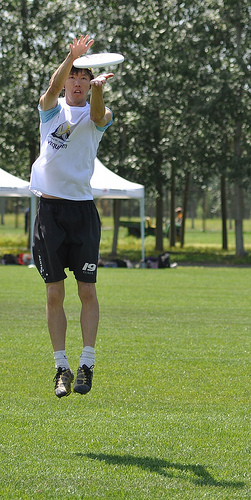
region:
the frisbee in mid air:
[72, 52, 123, 67]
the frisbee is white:
[73, 52, 124, 67]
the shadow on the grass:
[70, 452, 243, 487]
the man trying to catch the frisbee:
[28, 34, 123, 397]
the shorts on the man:
[31, 195, 101, 282]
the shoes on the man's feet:
[52, 364, 93, 397]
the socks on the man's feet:
[52, 345, 94, 371]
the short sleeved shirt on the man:
[28, 96, 112, 198]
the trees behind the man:
[0, 0, 250, 258]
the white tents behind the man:
[0, 156, 144, 267]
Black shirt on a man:
[31, 195, 101, 285]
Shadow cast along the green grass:
[71, 448, 247, 488]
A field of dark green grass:
[2, 266, 250, 498]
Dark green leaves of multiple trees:
[5, 4, 245, 173]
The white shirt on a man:
[29, 95, 111, 199]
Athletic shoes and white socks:
[50, 345, 96, 398]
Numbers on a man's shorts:
[81, 261, 95, 271]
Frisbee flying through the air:
[71, 52, 124, 69]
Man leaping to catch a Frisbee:
[27, 35, 124, 398]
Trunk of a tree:
[233, 188, 250, 257]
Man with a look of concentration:
[62, 64, 91, 106]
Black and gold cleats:
[36, 356, 103, 405]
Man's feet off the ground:
[46, 354, 99, 405]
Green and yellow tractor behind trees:
[119, 207, 182, 245]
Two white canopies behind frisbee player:
[0, 153, 150, 270]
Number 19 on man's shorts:
[76, 254, 98, 279]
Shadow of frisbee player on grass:
[75, 438, 247, 496]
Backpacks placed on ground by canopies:
[0, 248, 177, 272]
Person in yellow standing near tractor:
[172, 204, 188, 243]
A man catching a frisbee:
[16, 25, 135, 410]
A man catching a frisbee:
[14, 32, 127, 402]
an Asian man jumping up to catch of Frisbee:
[20, 15, 146, 464]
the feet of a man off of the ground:
[40, 358, 114, 467]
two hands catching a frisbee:
[64, 32, 128, 94]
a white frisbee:
[71, 52, 127, 71]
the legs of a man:
[37, 265, 109, 398]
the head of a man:
[67, 66, 89, 103]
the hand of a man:
[87, 72, 115, 90]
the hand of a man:
[61, 29, 94, 57]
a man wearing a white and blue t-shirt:
[28, 57, 106, 200]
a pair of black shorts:
[24, 189, 105, 285]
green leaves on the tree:
[204, 70, 238, 114]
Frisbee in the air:
[66, 37, 136, 74]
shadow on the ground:
[82, 428, 181, 486]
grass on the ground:
[124, 393, 201, 424]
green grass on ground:
[123, 385, 203, 426]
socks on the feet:
[34, 324, 116, 372]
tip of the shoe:
[69, 374, 100, 399]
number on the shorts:
[76, 253, 108, 280]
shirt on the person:
[19, 104, 112, 202]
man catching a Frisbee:
[28, 37, 162, 162]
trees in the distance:
[138, 98, 230, 181]